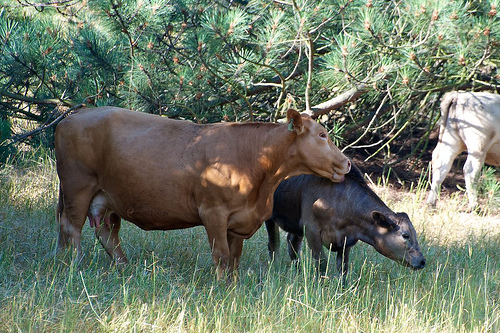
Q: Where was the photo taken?
A: It was taken at the field.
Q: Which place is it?
A: It is a field.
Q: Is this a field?
A: Yes, it is a field.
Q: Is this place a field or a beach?
A: It is a field.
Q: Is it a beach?
A: No, it is a field.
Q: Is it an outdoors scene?
A: Yes, it is outdoors.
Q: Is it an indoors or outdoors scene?
A: It is outdoors.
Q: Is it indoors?
A: No, it is outdoors.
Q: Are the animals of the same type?
A: Yes, all the animals are cows.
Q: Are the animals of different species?
A: No, all the animals are cows.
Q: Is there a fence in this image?
A: No, there are no fences.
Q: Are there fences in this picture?
A: No, there are no fences.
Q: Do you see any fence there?
A: No, there are no fences.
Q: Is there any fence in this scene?
A: No, there are no fences.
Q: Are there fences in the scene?
A: No, there are no fences.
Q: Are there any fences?
A: No, there are no fences.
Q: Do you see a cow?
A: Yes, there is a cow.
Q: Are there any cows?
A: Yes, there is a cow.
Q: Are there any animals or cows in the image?
A: Yes, there is a cow.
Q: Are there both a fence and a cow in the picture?
A: No, there is a cow but no fences.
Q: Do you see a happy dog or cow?
A: Yes, there is a happy cow.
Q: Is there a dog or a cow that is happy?
A: Yes, the cow is happy.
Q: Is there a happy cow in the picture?
A: Yes, there is a happy cow.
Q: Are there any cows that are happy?
A: Yes, there is a cow that is happy.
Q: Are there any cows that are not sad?
A: Yes, there is a happy cow.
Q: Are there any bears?
A: No, there are no bears.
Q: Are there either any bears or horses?
A: No, there are no bears or horses.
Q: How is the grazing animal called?
A: The animal is a cow.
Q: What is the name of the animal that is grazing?
A: The animal is a cow.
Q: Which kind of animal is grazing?
A: The animal is a cow.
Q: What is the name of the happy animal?
A: The animal is a cow.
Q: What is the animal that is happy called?
A: The animal is a cow.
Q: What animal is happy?
A: The animal is a cow.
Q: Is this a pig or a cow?
A: This is a cow.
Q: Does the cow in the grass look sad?
A: No, the cow is happy.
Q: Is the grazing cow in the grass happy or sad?
A: The cow is happy.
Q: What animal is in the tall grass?
A: The animal is a cow.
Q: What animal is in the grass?
A: The animal is a cow.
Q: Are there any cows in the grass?
A: Yes, there is a cow in the grass.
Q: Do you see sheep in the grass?
A: No, there is a cow in the grass.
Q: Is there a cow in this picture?
A: Yes, there is a cow.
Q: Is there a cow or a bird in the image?
A: Yes, there is a cow.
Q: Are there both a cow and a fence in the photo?
A: No, there is a cow but no fences.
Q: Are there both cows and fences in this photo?
A: No, there is a cow but no fences.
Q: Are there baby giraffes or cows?
A: Yes, there is a baby cow.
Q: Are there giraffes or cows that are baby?
A: Yes, the cow is a baby.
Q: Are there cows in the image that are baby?
A: Yes, there is a baby cow.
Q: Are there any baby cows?
A: Yes, there is a baby cow.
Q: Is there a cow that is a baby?
A: Yes, there is a cow that is a baby.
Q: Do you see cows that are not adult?
A: Yes, there is an baby cow.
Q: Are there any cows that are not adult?
A: Yes, there is an baby cow.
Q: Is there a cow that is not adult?
A: Yes, there is an baby cow.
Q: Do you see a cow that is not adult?
A: Yes, there is an baby cow.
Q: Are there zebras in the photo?
A: No, there are no zebras.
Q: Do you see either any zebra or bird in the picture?
A: No, there are no zebras or birds.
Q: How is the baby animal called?
A: The animal is a cow.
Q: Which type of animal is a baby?
A: The animal is a cow.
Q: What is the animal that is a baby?
A: The animal is a cow.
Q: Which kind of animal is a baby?
A: The animal is a cow.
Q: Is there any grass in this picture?
A: Yes, there is grass.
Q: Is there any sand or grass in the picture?
A: Yes, there is grass.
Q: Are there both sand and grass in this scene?
A: No, there is grass but no sand.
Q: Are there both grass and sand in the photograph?
A: No, there is grass but no sand.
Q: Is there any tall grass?
A: Yes, there is tall grass.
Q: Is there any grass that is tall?
A: Yes, there is grass that is tall.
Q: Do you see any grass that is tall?
A: Yes, there is grass that is tall.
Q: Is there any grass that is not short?
A: Yes, there is tall grass.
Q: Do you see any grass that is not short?
A: Yes, there is tall grass.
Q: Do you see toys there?
A: No, there are no toys.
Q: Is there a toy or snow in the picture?
A: No, there are no toys or snow.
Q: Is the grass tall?
A: Yes, the grass is tall.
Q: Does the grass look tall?
A: Yes, the grass is tall.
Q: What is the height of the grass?
A: The grass is tall.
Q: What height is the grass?
A: The grass is tall.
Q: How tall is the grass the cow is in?
A: The grass is tall.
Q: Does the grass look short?
A: No, the grass is tall.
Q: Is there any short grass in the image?
A: No, there is grass but it is tall.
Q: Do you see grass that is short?
A: No, there is grass but it is tall.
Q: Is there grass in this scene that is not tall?
A: No, there is grass but it is tall.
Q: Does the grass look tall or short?
A: The grass is tall.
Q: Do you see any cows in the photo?
A: Yes, there is a cow.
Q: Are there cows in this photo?
A: Yes, there is a cow.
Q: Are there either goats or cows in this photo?
A: Yes, there is a cow.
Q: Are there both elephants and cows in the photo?
A: No, there is a cow but no elephants.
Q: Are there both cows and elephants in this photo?
A: No, there is a cow but no elephants.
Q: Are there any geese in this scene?
A: No, there are no geese.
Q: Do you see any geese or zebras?
A: No, there are no geese or zebras.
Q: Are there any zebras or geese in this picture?
A: No, there are no geese or zebras.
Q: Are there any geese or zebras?
A: No, there are no geese or zebras.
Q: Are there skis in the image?
A: No, there are no skis.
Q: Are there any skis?
A: No, there are no skis.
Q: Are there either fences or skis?
A: No, there are no skis or fences.